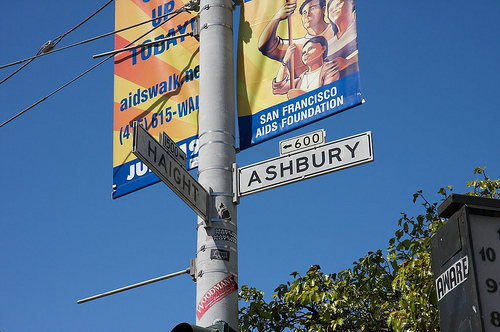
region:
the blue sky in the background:
[5, 197, 181, 259]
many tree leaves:
[262, 260, 422, 325]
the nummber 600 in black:
[291, 135, 318, 145]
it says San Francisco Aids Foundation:
[253, 83, 340, 135]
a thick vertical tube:
[195, 2, 236, 317]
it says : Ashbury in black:
[245, 135, 366, 188]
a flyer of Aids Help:
[110, 3, 361, 138]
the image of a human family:
[263, 0, 358, 91]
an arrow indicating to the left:
[282, 142, 289, 147]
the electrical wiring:
[1, 22, 106, 124]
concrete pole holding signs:
[201, 5, 247, 330]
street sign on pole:
[124, 136, 216, 215]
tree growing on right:
[251, 181, 498, 330]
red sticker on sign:
[190, 275, 242, 307]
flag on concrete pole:
[245, 10, 352, 127]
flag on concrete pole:
[110, 4, 198, 184]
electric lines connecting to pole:
[2, 7, 134, 126]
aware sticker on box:
[425, 257, 487, 298]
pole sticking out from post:
[74, 268, 204, 296]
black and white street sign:
[233, 128, 370, 196]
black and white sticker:
[435, 257, 470, 299]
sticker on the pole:
[195, 273, 235, 315]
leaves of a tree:
[237, 166, 498, 330]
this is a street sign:
[132, 120, 209, 219]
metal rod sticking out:
[73, 268, 189, 303]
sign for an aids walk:
[112, 0, 358, 197]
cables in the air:
[0, 0, 197, 127]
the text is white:
[255, 85, 342, 135]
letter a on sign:
[248, 166, 263, 191]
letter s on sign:
[266, 160, 278, 185]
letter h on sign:
[277, 159, 294, 179]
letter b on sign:
[293, 153, 308, 175]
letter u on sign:
[311, 148, 328, 169]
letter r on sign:
[326, 145, 343, 169]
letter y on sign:
[343, 138, 362, 158]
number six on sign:
[292, 133, 303, 150]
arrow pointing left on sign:
[281, 141, 292, 152]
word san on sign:
[257, 106, 280, 123]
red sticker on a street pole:
[187, 273, 235, 317]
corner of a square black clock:
[417, 189, 498, 330]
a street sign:
[234, 121, 375, 208]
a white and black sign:
[130, 128, 217, 223]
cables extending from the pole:
[0, 0, 199, 145]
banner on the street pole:
[102, 0, 372, 197]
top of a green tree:
[220, 164, 497, 330]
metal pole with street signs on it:
[134, 0, 371, 328]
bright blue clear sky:
[4, 5, 488, 322]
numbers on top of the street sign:
[276, 126, 325, 152]